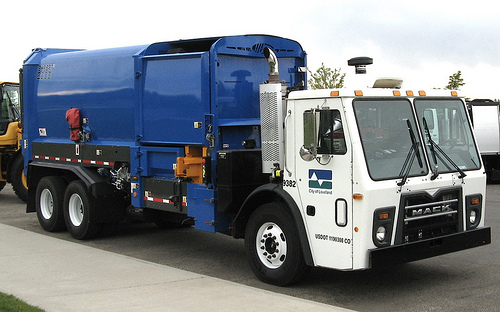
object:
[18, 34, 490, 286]
truck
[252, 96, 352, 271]
door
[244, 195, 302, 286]
tire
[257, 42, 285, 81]
pipe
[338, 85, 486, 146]
windshield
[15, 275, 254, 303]
road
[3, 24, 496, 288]
picture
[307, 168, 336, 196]
logo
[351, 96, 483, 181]
window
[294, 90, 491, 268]
cab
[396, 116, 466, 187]
wipers